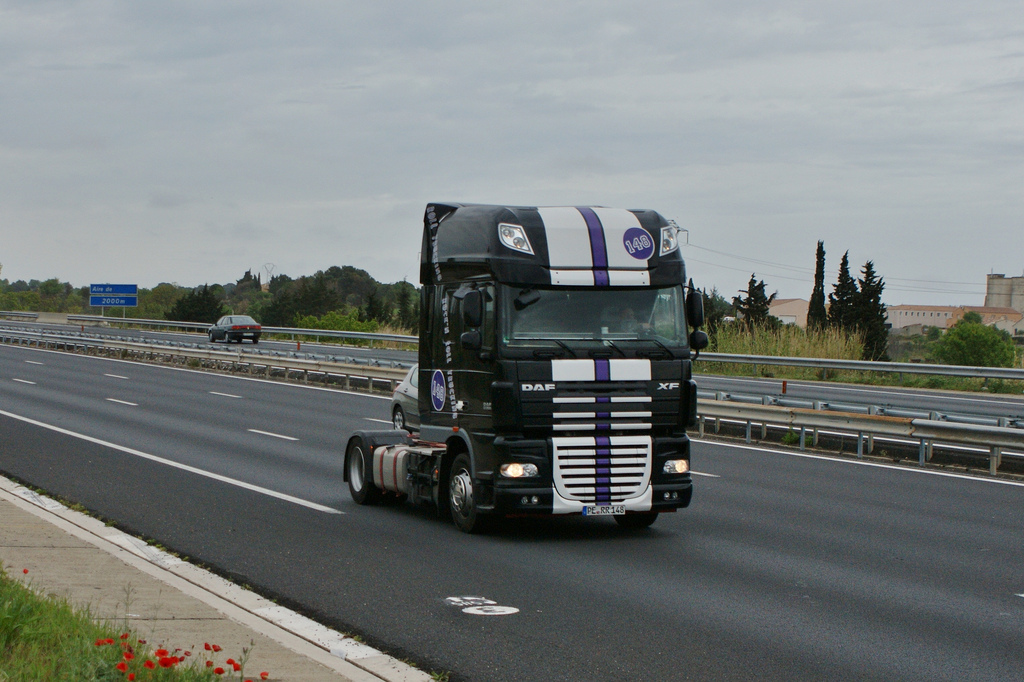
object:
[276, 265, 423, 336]
tree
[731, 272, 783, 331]
tree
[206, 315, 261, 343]
car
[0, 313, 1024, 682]
highway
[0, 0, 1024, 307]
clouds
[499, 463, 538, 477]
headlight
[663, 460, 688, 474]
headlight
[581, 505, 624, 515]
plate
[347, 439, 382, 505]
tire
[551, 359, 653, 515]
grill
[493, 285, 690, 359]
cab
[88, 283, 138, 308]
sign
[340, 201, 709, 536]
truck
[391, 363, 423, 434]
vehicle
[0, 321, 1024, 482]
rail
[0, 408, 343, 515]
line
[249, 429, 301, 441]
lines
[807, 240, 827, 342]
tree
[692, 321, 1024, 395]
field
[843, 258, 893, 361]
tree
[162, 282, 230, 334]
tree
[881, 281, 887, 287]
leaves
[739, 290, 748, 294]
leaves